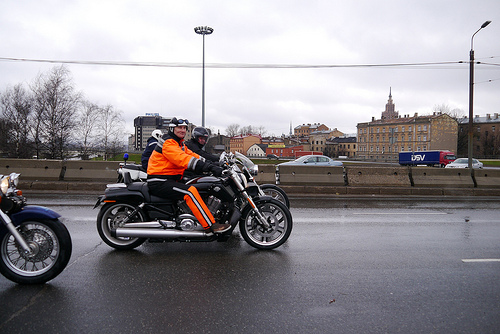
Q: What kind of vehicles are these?
A: Motorcycles.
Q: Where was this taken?
A: On street.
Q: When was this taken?
A: Day time.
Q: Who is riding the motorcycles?
A: Men.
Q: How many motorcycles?
A: Three.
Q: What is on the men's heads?
A: Helmets.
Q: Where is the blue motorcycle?
A: Lower left corner.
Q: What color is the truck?
A: Red.